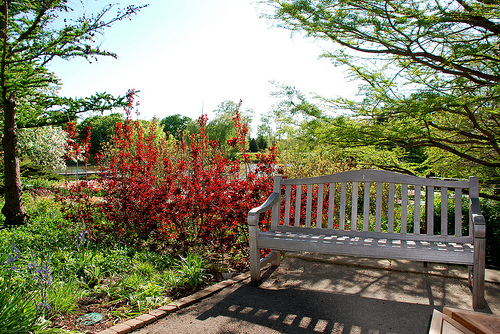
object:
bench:
[250, 167, 486, 311]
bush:
[0, 266, 78, 333]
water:
[62, 159, 294, 183]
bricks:
[147, 308, 167, 320]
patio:
[0, 0, 499, 333]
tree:
[0, 0, 150, 227]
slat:
[387, 182, 395, 234]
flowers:
[71, 229, 93, 248]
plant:
[54, 120, 96, 223]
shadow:
[194, 264, 444, 333]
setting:
[0, 0, 499, 333]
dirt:
[48, 248, 237, 333]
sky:
[3, 0, 499, 140]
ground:
[0, 177, 499, 333]